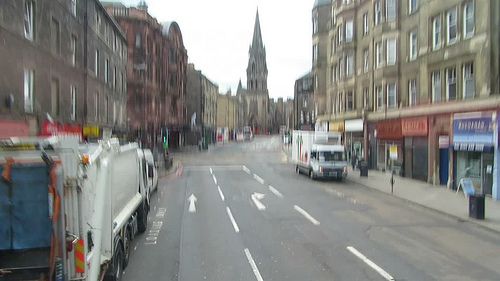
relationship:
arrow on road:
[186, 191, 199, 213] [120, 134, 499, 280]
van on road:
[292, 127, 346, 182] [120, 134, 499, 280]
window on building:
[22, 64, 37, 117] [0, 2, 129, 144]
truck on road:
[1, 135, 150, 278] [120, 134, 499, 280]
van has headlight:
[292, 127, 346, 182] [318, 164, 323, 172]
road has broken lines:
[120, 134, 499, 280] [242, 162, 395, 280]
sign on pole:
[388, 141, 400, 160] [389, 170, 396, 193]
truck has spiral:
[1, 135, 150, 278] [72, 237, 86, 274]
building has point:
[233, 7, 294, 133] [243, 7, 269, 71]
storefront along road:
[453, 111, 497, 198] [120, 134, 499, 280]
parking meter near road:
[389, 170, 396, 193] [120, 134, 499, 280]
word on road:
[144, 204, 169, 245] [120, 134, 499, 280]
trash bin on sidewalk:
[467, 191, 486, 219] [344, 158, 499, 235]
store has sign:
[376, 117, 404, 174] [375, 117, 404, 141]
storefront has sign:
[453, 111, 497, 198] [451, 114, 494, 144]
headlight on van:
[344, 165, 349, 172] [292, 127, 346, 182]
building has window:
[0, 2, 129, 144] [22, 64, 37, 117]